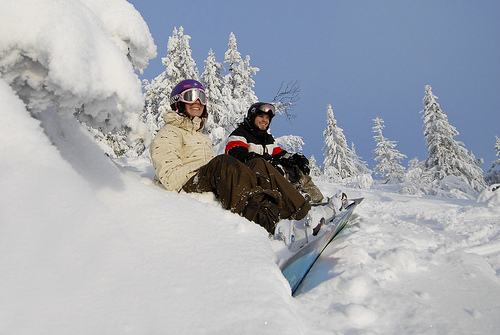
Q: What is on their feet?
A: Snowboards.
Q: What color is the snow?
A: White.